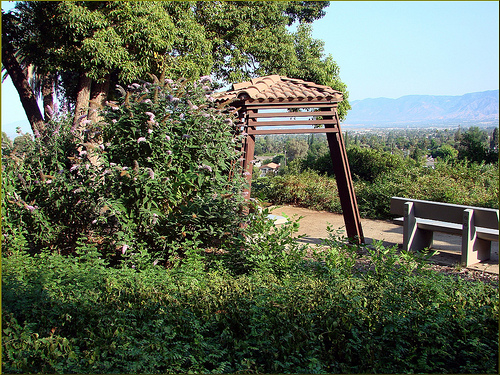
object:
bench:
[390, 196, 500, 267]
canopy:
[208, 73, 345, 103]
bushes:
[234, 214, 320, 371]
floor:
[266, 205, 329, 242]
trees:
[431, 144, 459, 168]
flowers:
[78, 141, 98, 154]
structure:
[232, 106, 366, 246]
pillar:
[326, 132, 365, 246]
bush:
[426, 268, 500, 375]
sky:
[333, 17, 474, 87]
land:
[263, 199, 421, 240]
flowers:
[142, 111, 160, 130]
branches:
[72, 39, 125, 81]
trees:
[84, 2, 178, 250]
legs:
[234, 134, 255, 250]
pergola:
[206, 75, 365, 251]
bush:
[150, 101, 248, 265]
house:
[259, 162, 279, 173]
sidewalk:
[267, 201, 499, 286]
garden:
[0, 1, 499, 373]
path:
[268, 195, 498, 284]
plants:
[1, 0, 49, 163]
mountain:
[339, 89, 498, 131]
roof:
[207, 75, 342, 108]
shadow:
[297, 234, 464, 267]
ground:
[267, 199, 499, 284]